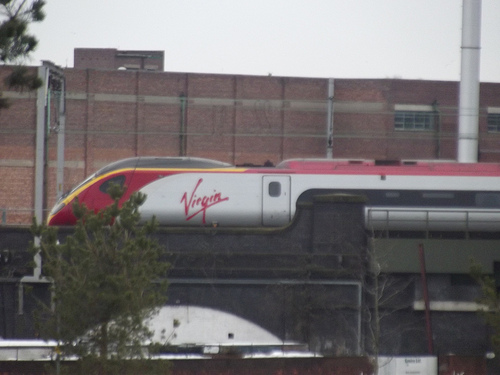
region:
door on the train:
[258, 173, 298, 225]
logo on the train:
[178, 178, 228, 231]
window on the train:
[383, 192, 401, 199]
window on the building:
[392, 100, 437, 132]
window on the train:
[424, 188, 454, 198]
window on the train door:
[268, 181, 280, 196]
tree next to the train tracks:
[22, 165, 205, 365]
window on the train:
[98, 171, 123, 201]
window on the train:
[475, 194, 496, 209]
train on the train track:
[41, 142, 495, 234]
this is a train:
[40, 102, 497, 264]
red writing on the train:
[163, 162, 260, 238]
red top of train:
[245, 135, 490, 185]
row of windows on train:
[302, 187, 499, 216]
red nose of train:
[54, 156, 161, 230]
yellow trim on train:
[60, 150, 254, 190]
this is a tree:
[20, 156, 170, 373]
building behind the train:
[35, 14, 493, 270]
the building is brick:
[45, 64, 444, 209]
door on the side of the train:
[253, 167, 304, 224]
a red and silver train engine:
[45, 152, 498, 234]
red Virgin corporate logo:
[179, 178, 231, 224]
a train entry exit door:
[261, 175, 293, 228]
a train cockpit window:
[98, 173, 124, 193]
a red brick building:
[0, 65, 496, 222]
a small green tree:
[34, 183, 167, 373]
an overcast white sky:
[1, 0, 498, 81]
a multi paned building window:
[394, 113, 431, 130]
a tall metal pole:
[456, 2, 483, 163]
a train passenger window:
[474, 190, 499, 207]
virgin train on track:
[42, 153, 498, 271]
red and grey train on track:
[45, 141, 495, 229]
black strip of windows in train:
[295, 186, 497, 222]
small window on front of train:
[98, 165, 136, 200]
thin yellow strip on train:
[36, 135, 248, 231]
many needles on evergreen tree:
[20, 176, 193, 361]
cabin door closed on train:
[254, 162, 302, 231]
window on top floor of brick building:
[366, 97, 444, 140]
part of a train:
[418, 157, 428, 170]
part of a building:
[273, 170, 275, 180]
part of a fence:
[318, 315, 327, 332]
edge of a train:
[318, 273, 322, 287]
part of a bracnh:
[361, 290, 381, 320]